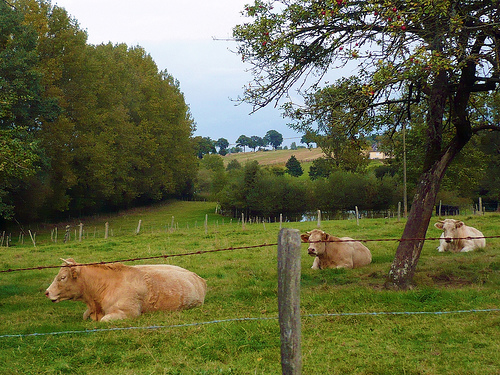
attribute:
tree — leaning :
[205, 0, 498, 291]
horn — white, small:
[52, 252, 77, 274]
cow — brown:
[26, 240, 243, 362]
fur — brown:
[109, 277, 166, 294]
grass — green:
[3, 196, 498, 372]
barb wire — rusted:
[309, 234, 498, 247]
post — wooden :
[267, 216, 323, 313]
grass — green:
[310, 319, 492, 373]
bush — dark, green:
[214, 176, 253, 216]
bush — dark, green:
[247, 161, 297, 213]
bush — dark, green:
[288, 172, 333, 214]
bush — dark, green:
[318, 165, 397, 212]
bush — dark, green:
[193, 163, 231, 202]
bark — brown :
[416, 170, 435, 200]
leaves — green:
[132, 182, 139, 191]